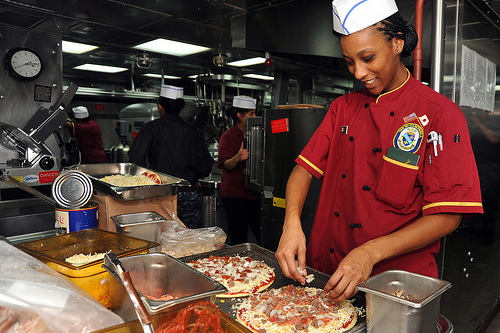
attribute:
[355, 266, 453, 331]
container — silver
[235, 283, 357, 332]
pizza — uncooked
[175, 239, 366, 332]
tray — silver, metal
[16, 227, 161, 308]
container — yellow, gold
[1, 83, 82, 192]
deli slicer — silver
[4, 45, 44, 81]
clock — black, round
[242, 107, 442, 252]
oven — silver, industrial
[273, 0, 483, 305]
woman — smiling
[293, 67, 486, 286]
shirt — red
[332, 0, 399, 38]
hat — paper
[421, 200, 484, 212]
trim — yellow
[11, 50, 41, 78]
clock face — white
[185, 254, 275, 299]
pizza — uncooked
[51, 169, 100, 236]
can — open, metal, blue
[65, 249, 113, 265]
cheese — shredded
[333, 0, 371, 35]
stripe — blue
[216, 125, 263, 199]
uniform — red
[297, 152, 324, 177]
trim — yellow